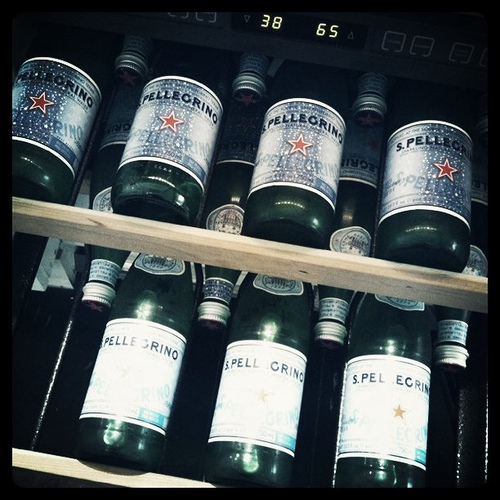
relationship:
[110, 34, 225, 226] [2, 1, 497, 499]
beer in a cooler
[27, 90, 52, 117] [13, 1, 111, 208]
star on a bottle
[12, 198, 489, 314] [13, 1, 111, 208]
shelf holding bottle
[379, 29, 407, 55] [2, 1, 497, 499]
button on cooler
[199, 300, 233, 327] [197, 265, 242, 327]
lid to bottle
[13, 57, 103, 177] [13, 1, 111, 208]
label on bottle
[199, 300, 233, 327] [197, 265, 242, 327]
lid of bottle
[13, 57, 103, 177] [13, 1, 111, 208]
label of bottle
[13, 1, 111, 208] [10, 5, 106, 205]
bottle of wine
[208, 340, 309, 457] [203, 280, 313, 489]
label on bottle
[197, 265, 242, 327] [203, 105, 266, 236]
bottle of water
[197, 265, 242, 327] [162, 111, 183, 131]
bottle has star